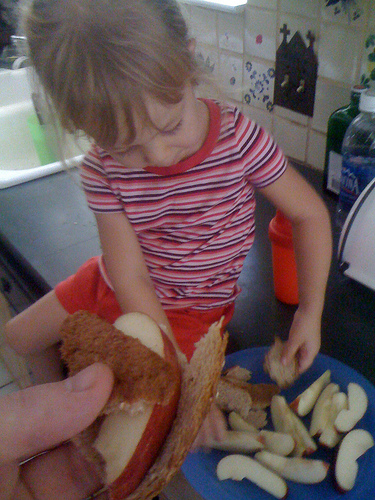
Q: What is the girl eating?
A: Apples.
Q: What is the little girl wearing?
A: A red striped shirt.